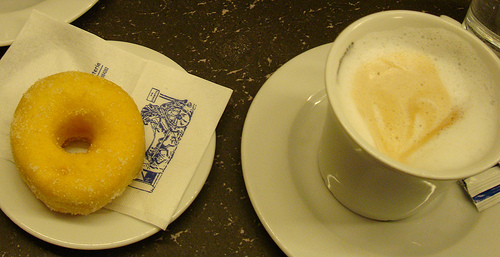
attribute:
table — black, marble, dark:
[0, 2, 499, 255]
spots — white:
[1, 1, 469, 255]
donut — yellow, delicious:
[9, 71, 146, 215]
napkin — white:
[1, 8, 235, 233]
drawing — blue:
[89, 61, 197, 194]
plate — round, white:
[0, 40, 217, 250]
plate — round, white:
[240, 42, 499, 256]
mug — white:
[315, 9, 499, 223]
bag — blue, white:
[459, 163, 499, 212]